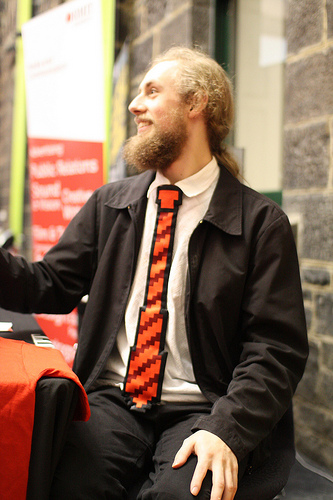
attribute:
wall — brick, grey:
[287, 3, 331, 212]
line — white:
[288, 36, 328, 61]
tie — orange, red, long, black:
[119, 187, 185, 411]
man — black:
[11, 45, 313, 496]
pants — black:
[51, 381, 276, 499]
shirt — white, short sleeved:
[99, 172, 208, 407]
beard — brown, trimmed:
[122, 120, 191, 169]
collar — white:
[176, 151, 225, 196]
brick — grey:
[283, 0, 323, 44]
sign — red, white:
[21, 0, 109, 242]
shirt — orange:
[0, 334, 96, 498]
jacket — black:
[1, 160, 320, 446]